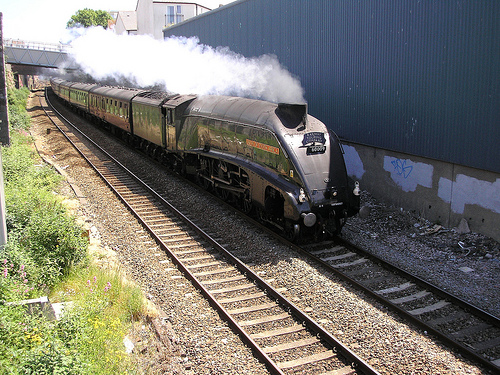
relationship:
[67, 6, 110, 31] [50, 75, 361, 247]
tree behind train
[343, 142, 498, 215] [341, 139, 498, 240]
patches on cement fundation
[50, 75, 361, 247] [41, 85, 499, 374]
train on track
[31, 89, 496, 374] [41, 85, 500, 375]
gravel along track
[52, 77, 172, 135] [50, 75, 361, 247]
windows on train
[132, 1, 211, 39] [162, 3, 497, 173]
building in back of fence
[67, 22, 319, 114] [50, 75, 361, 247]
smoke in train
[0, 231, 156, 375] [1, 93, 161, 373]
patch of grass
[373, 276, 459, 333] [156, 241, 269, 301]
part of brown tracks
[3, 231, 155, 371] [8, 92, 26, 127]
patch of grass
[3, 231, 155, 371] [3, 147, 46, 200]
patch of grass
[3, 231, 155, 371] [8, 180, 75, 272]
patch of grass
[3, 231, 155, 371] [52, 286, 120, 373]
patch of grass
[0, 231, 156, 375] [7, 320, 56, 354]
patch of grass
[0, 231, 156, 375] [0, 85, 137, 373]
patch of grass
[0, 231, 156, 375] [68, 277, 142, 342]
patch of grass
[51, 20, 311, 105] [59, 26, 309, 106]
cloud of smoke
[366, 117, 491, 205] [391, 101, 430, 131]
brick wall with white brushes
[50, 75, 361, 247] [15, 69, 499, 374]
train on tracks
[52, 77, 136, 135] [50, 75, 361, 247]
windows in train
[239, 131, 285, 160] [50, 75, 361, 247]
label in train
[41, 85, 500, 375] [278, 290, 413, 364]
track on gravel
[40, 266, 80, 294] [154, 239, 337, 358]
grass next to tracks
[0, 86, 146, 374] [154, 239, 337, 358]
green bushes next to tracks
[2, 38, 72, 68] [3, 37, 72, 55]
bridge with rails